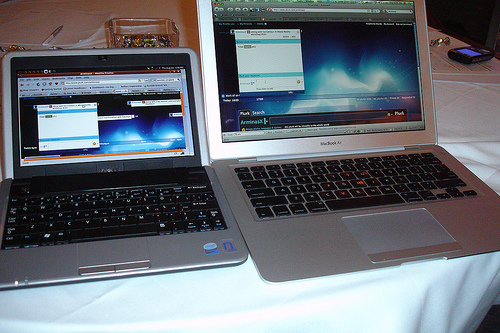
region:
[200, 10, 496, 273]
one grey laptop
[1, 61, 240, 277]
one smaller grey laptop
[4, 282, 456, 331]
a white table cloth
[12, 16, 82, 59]
a pen on a table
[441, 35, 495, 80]
a lit phone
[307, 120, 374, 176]
a Macbook sign on a laptop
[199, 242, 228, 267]
an Intel sticker on a small laptop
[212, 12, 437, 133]
a laptop screen using internet explorer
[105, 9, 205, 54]
a square glass bowl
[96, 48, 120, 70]
a laptop has a camera on the top of the screen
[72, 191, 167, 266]
black keyboard on laptop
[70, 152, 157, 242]
black keyboard on laptop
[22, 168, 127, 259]
black keyboard on laptop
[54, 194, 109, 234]
black keyboard on laptop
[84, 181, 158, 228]
black keyboard on laptop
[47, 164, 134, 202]
black keyboard on laptop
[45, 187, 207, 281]
black keyboard on laptop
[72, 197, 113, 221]
black keyboard on laptop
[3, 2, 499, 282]
computers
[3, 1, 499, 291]
two computers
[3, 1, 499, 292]
two laptop computers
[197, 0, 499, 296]
the laptop on the right is a MacBook Air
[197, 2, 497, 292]
the laptop on the right is made by Apple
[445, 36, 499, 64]
a cellphone is on the table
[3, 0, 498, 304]
the computers are on the edge of a table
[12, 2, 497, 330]
the table has a white tablecloth on it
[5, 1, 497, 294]
both laptops are powered on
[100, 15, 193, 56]
a container of candy is behind the computers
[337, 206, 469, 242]
Touchpad on a notebook computer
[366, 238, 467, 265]
Mouse buttons on a notebook computer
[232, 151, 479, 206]
Keyboard on a notebook computer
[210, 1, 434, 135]
Display screen on a notebook computer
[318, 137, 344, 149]
Manufacturer logo on a notebook computer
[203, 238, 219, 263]
Software sticker on a notebook computer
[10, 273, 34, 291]
Indicator lights on a notebook computer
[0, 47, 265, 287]
Notebook computer sitting on a tabletop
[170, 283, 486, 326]
Tablecloth on a table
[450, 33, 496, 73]
Electronic device sitting on a tabletop